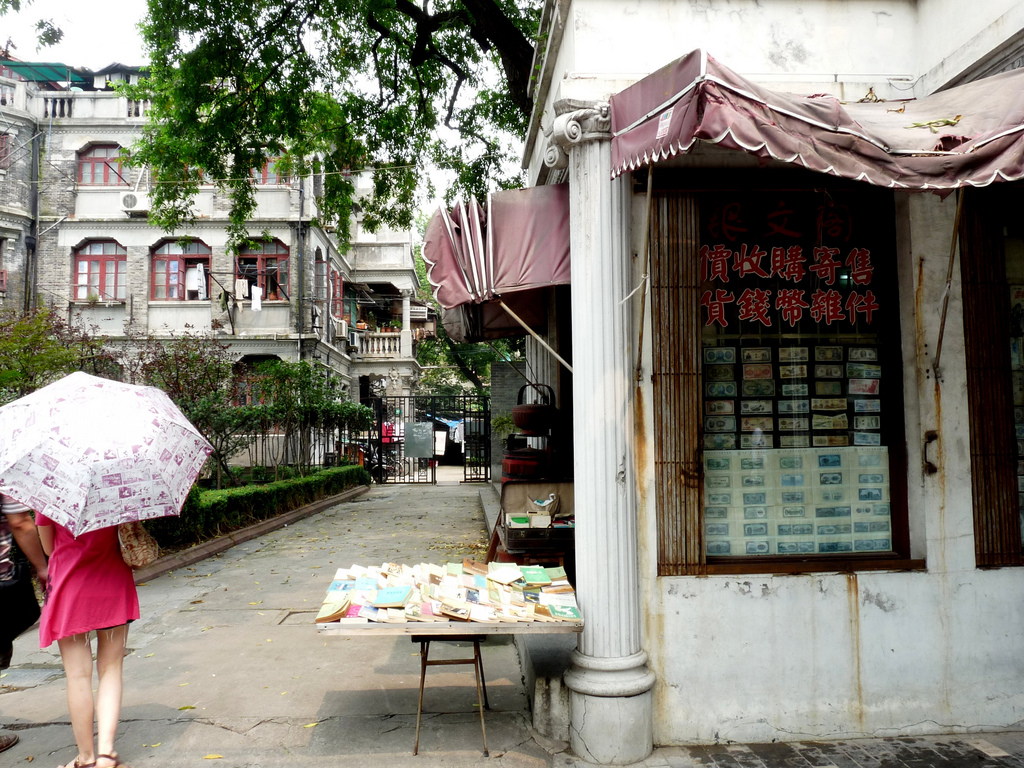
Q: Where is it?
A: This is at the store.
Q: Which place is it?
A: It is a store.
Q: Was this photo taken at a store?
A: Yes, it was taken in a store.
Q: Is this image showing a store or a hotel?
A: It is showing a store.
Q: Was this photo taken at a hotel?
A: No, the picture was taken in a store.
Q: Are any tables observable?
A: Yes, there is a table.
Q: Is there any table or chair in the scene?
A: Yes, there is a table.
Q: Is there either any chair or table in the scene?
A: Yes, there is a table.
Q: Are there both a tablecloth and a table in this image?
A: No, there is a table but no tablecloths.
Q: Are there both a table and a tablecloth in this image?
A: No, there is a table but no tablecloths.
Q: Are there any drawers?
A: No, there are no drawers.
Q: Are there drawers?
A: No, there are no drawers.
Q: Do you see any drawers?
A: No, there are no drawers.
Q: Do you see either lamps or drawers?
A: No, there are no drawers or lamps.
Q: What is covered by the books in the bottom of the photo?
A: The table is covered by the books.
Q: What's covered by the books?
A: The table is covered by the books.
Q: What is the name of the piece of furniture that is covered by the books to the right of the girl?
A: The piece of furniture is a table.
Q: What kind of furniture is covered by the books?
A: The piece of furniture is a table.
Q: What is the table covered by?
A: The table is covered by the books.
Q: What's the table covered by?
A: The table is covered by the books.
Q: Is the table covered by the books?
A: Yes, the table is covered by the books.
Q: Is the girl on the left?
A: Yes, the girl is on the left of the image.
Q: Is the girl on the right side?
A: No, the girl is on the left of the image.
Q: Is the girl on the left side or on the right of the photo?
A: The girl is on the left of the image.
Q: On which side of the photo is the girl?
A: The girl is on the left of the image.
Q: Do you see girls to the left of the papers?
A: Yes, there is a girl to the left of the papers.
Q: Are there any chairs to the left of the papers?
A: No, there is a girl to the left of the papers.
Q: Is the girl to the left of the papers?
A: Yes, the girl is to the left of the papers.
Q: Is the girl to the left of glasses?
A: No, the girl is to the left of the papers.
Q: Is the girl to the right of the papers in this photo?
A: No, the girl is to the left of the papers.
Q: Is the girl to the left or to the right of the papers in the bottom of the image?
A: The girl is to the left of the papers.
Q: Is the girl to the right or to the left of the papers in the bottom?
A: The girl is to the left of the papers.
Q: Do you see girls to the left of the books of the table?
A: Yes, there is a girl to the left of the books.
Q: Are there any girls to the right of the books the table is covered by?
A: No, the girl is to the left of the books.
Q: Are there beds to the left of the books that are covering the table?
A: No, there is a girl to the left of the books.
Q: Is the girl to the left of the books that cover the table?
A: Yes, the girl is to the left of the books.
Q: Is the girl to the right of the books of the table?
A: No, the girl is to the left of the books.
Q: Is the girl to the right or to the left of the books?
A: The girl is to the left of the books.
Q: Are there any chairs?
A: No, there are no chairs.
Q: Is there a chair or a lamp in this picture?
A: No, there are no chairs or lamps.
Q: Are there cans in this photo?
A: No, there are no cans.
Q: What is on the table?
A: The papers are on the table.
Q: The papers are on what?
A: The papers are on the table.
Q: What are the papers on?
A: The papers are on the table.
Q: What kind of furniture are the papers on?
A: The papers are on the table.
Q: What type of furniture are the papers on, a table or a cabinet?
A: The papers are on a table.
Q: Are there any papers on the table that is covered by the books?
A: Yes, there are papers on the table.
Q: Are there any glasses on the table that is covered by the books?
A: No, there are papers on the table.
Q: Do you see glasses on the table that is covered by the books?
A: No, there are papers on the table.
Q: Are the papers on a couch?
A: No, the papers are on the table.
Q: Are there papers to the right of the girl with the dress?
A: Yes, there are papers to the right of the girl.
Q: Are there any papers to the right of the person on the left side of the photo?
A: Yes, there are papers to the right of the girl.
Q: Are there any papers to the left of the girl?
A: No, the papers are to the right of the girl.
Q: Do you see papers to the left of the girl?
A: No, the papers are to the right of the girl.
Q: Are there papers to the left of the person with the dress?
A: No, the papers are to the right of the girl.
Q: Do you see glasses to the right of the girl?
A: No, there are papers to the right of the girl.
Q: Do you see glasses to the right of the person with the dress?
A: No, there are papers to the right of the girl.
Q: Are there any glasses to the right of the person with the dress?
A: No, there are papers to the right of the girl.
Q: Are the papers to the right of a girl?
A: Yes, the papers are to the right of a girl.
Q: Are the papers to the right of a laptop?
A: No, the papers are to the right of a girl.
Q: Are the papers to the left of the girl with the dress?
A: No, the papers are to the right of the girl.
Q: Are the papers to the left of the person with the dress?
A: No, the papers are to the right of the girl.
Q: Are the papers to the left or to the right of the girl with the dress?
A: The papers are to the right of the girl.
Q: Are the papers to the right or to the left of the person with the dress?
A: The papers are to the right of the girl.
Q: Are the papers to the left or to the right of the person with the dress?
A: The papers are to the right of the girl.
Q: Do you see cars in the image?
A: No, there are no cars.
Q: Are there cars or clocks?
A: No, there are no cars or clocks.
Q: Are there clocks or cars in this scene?
A: No, there are no cars or clocks.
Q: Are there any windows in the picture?
A: Yes, there are windows.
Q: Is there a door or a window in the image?
A: Yes, there are windows.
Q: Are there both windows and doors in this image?
A: No, there are windows but no doors.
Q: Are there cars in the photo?
A: No, there are no cars.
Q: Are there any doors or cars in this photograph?
A: No, there are no cars or doors.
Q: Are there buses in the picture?
A: No, there are no buses.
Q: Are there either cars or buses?
A: No, there are no buses or cars.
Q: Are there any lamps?
A: No, there are no lamps.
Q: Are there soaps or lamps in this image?
A: No, there are no lamps or soaps.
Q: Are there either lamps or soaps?
A: No, there are no lamps or soaps.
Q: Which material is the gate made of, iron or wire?
A: The gate is made of iron.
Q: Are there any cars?
A: No, there are no cars.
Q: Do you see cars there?
A: No, there are no cars.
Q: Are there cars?
A: No, there are no cars.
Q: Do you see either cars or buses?
A: No, there are no cars or buses.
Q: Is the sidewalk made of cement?
A: Yes, the sidewalk is made of cement.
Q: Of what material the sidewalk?
A: The sidewalk is made of concrete.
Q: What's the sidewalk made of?
A: The sidewalk is made of concrete.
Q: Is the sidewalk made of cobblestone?
A: No, the sidewalk is made of concrete.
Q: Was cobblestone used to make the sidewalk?
A: No, the sidewalk is made of concrete.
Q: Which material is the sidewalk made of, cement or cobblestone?
A: The sidewalk is made of cement.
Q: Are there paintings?
A: No, there are no paintings.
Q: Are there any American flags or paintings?
A: No, there are no paintings or American flags.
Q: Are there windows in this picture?
A: Yes, there is a window.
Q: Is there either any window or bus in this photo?
A: Yes, there is a window.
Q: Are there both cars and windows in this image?
A: No, there is a window but no cars.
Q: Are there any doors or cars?
A: No, there are no cars or doors.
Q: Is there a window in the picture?
A: Yes, there is a window.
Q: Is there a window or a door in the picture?
A: Yes, there is a window.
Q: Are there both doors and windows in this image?
A: No, there is a window but no doors.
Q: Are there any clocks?
A: No, there are no clocks.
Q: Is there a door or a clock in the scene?
A: No, there are no clocks or doors.